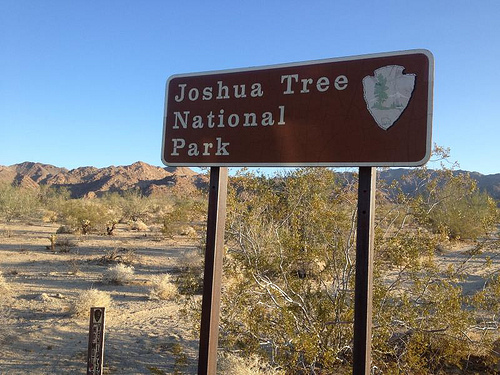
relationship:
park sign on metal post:
[158, 50, 434, 166] [168, 68, 435, 368]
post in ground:
[88, 308, 104, 373] [6, 212, 487, 372]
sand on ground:
[6, 208, 192, 297] [6, 212, 487, 372]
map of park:
[362, 66, 420, 138] [11, 175, 496, 365]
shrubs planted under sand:
[4, 186, 224, 250] [0, 189, 205, 332]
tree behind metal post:
[218, 163, 495, 367] [351, 165, 377, 374]